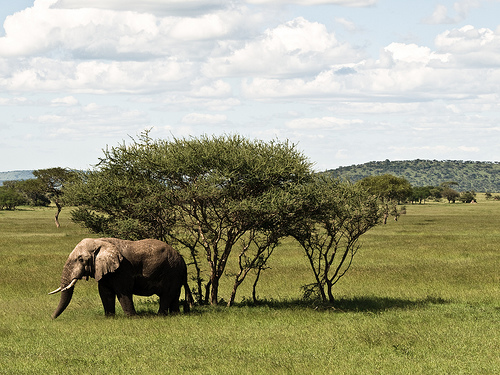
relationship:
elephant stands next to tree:
[50, 235, 188, 316] [58, 140, 308, 302]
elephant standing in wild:
[50, 235, 188, 316] [12, 191, 494, 375]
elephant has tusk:
[50, 235, 188, 316] [61, 276, 79, 298]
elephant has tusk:
[50, 235, 188, 316] [49, 284, 63, 295]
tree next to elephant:
[58, 140, 308, 302] [50, 235, 188, 316]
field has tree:
[4, 192, 498, 375] [456, 193, 479, 206]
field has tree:
[4, 192, 498, 375] [445, 190, 466, 204]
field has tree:
[4, 192, 498, 375] [358, 173, 412, 222]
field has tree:
[4, 192, 498, 375] [34, 167, 88, 225]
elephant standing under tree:
[50, 235, 188, 316] [58, 140, 308, 302]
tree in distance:
[456, 193, 479, 206] [333, 162, 491, 230]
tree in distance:
[445, 190, 466, 204] [333, 162, 491, 230]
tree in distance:
[358, 173, 412, 222] [333, 162, 491, 230]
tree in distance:
[416, 188, 444, 203] [333, 162, 491, 230]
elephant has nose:
[50, 235, 188, 316] [53, 265, 80, 320]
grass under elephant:
[2, 195, 495, 374] [50, 235, 188, 316]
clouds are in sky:
[0, 8, 495, 137] [3, 0, 500, 189]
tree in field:
[58, 140, 308, 302] [4, 192, 498, 375]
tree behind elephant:
[58, 140, 308, 302] [50, 235, 188, 316]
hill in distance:
[314, 157, 497, 203] [333, 162, 491, 230]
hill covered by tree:
[314, 157, 497, 203] [474, 165, 496, 185]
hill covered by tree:
[314, 157, 497, 203] [427, 161, 457, 182]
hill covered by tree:
[314, 157, 497, 203] [352, 165, 374, 179]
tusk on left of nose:
[61, 276, 79, 298] [53, 265, 80, 320]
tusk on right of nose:
[49, 284, 63, 295] [53, 265, 80, 320]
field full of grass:
[4, 192, 498, 375] [2, 195, 495, 374]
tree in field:
[358, 173, 412, 222] [4, 192, 498, 375]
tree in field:
[416, 188, 444, 203] [4, 192, 498, 375]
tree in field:
[445, 190, 466, 204] [4, 192, 498, 375]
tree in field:
[456, 193, 479, 206] [4, 192, 498, 375]